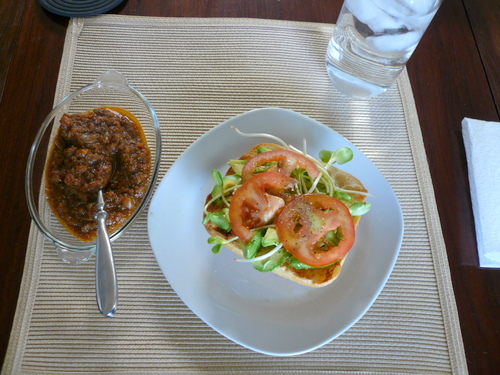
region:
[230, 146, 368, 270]
red vegetable on plate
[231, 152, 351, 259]
vegetable is a tomato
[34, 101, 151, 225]
brown food in bowl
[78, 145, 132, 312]
spoon in the bowl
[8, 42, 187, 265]
bowl is made of glass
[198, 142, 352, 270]
green vegetable is unnderneath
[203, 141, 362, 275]
vegetables are on bread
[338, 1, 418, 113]
water in the glass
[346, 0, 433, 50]
ice in the glass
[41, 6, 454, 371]
table cloth under the plate and bowl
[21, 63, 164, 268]
glass bowl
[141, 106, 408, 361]
white plate holding food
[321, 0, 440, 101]
glass holding water and ice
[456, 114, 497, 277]
white folded napkin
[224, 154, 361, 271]
sliced tomatoes on the bread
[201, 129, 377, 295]
greens under the tomatoes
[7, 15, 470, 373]
kacki colored place mat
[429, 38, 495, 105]
wooden topped table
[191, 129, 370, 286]
slice of bread on the bottom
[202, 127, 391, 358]
a healthy sandwich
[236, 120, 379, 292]
tomatoes & sprouts are on the flat bread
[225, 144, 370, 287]
the flatbread appears to be toasted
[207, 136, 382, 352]
the plate is white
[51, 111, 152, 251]
it appears there is chili in the bowl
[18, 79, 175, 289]
the bowl is clear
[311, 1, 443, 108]
a glass of ice water is on the table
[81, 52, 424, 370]
the place mat is beige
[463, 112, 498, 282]
a napkin is to the far right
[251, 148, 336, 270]
the tomatoes have pepper on them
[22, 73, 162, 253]
Bowl of Hot Sauce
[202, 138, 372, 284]
Open Faced Sandwich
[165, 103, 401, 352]
Open Faced Sandwich on White Plate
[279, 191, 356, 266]
Slice of Red Tomato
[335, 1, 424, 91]
Glass of Ice Water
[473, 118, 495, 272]
White Dinner Napkin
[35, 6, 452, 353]
Meal served on tan placemat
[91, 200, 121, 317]
Silver Handle of Serving Utensil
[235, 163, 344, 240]
Sliced Tomatoes and Micro Greens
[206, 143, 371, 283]
Sliced Red Tomatoes and Micro Greens on Bread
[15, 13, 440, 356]
the fixings for a taco salad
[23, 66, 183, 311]
a bowl of taco meat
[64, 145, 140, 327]
a silver colored spoon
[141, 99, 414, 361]
a white bowl with food in it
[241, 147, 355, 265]
several slices of tomato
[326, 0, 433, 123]
a glass of ice water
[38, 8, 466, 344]
a white place mat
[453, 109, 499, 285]
a white table napkin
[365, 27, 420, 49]
a cold piece of ice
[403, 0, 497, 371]
a wooden table top